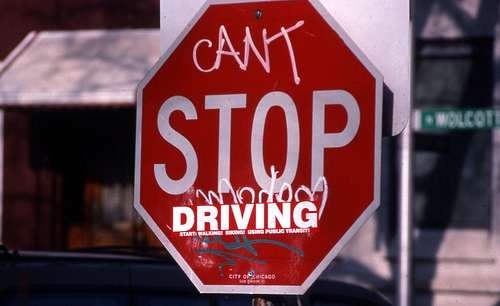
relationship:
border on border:
[199, 281, 310, 294] [131, 82, 144, 208]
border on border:
[301, 57, 384, 284] [131, 82, 144, 208]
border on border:
[131, 10, 201, 285] [131, 82, 144, 208]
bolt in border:
[254, 10, 263, 19] [131, 82, 144, 208]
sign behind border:
[156, 8, 416, 138] [131, 82, 144, 208]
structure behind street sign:
[412, 224, 484, 303] [390, 95, 484, 295]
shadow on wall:
[421, 27, 484, 224] [417, 213, 485, 297]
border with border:
[131, 82, 144, 208] [196, 279, 302, 298]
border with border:
[131, 82, 144, 208] [300, 3, 383, 290]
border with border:
[131, 82, 144, 208] [132, 4, 203, 298]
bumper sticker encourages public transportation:
[169, 198, 326, 245] [180, 228, 313, 236]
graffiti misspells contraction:
[150, 14, 360, 280] [188, 20, 308, 82]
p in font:
[309, 87, 359, 199] [152, 89, 364, 201]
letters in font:
[154, 95, 199, 195] [151, 86, 363, 192]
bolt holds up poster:
[252, 10, 262, 20] [128, 2, 387, 296]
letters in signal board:
[154, 95, 362, 194] [134, 2, 384, 292]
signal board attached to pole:
[134, 2, 384, 292] [254, 295, 272, 304]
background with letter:
[419, 109, 498, 127] [474, 112, 486, 126]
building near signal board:
[0, 24, 166, 239] [134, 2, 384, 292]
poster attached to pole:
[128, 2, 387, 296] [252, 296, 273, 304]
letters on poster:
[154, 95, 362, 194] [128, 2, 387, 296]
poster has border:
[128, 2, 387, 296] [199, 281, 310, 294]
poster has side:
[128, 2, 387, 296] [295, 201, 380, 294]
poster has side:
[128, 2, 387, 296] [366, 72, 387, 206]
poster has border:
[128, 2, 387, 296] [131, 82, 144, 208]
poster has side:
[128, 2, 387, 296] [137, 0, 207, 90]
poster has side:
[128, 2, 387, 296] [304, 1, 386, 81]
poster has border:
[128, 2, 387, 296] [205, 0, 274, 6]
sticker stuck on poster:
[174, 203, 323, 232] [128, 2, 387, 296]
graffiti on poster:
[150, 14, 360, 280] [128, 2, 387, 296]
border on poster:
[370, 73, 384, 202] [128, 2, 387, 296]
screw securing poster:
[247, 269, 256, 277] [128, 2, 387, 296]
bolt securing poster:
[254, 10, 263, 19] [128, 2, 387, 296]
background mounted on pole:
[422, 109, 499, 131] [395, 112, 412, 303]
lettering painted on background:
[425, 110, 485, 131] [422, 109, 499, 131]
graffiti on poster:
[189, 14, 314, 280] [128, 2, 387, 296]